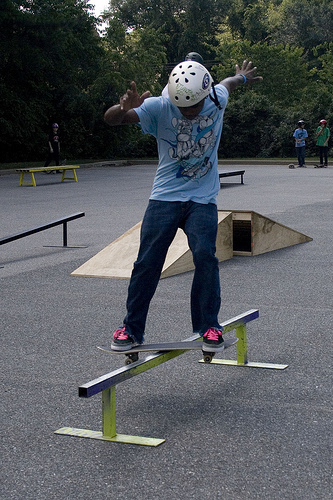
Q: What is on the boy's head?
A: A helmet.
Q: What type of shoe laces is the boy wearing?
A: Bright pink.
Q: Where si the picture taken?
A: A skate park.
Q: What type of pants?
A: Jeans.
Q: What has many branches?
A: Trees.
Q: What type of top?
A: Shirt.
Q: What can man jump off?
A: Ramp.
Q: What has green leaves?
A: Tree.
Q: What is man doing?
A: Skateboarding.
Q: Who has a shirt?
A: The boy.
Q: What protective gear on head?
A: Helmet.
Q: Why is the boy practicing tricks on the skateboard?
A: In order to better his foot placement on the skateboard.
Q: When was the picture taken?
A: Daytime.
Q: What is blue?
A: Skateboarder's shirt.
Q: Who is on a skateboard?
A: A boy.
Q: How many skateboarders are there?
A: One.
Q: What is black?
A: Skateboard.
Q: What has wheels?
A: A skateboard.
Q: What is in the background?
A: Trees.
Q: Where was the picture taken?
A: A skate park.